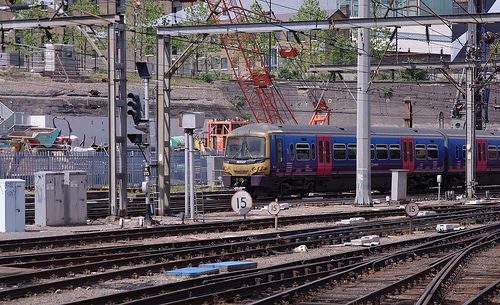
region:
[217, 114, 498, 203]
A red, yellow, blue and gray train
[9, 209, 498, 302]
A group of railroad tracks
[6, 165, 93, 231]
Three gray metal boxes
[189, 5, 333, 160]
A red construction vehicle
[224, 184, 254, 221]
Round sign with the number 15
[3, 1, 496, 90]
Trees and buildings behind a fence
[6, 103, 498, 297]
Train stopped at a railroad station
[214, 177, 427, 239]
Three circular signs with the number 15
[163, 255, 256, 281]
Two blue concrete squares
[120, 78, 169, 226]
Traffic light with no lights lit up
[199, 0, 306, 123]
red structure above train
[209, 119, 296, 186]
front of train is yellow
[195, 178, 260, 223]
the sign is white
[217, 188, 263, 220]
the sign is circular shaped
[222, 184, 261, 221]
black numbers on sign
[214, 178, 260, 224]
red circle around sign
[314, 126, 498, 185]
the train doors are red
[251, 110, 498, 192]
the train is blue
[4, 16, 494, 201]
structure is made of metal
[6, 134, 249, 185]
fence beside the train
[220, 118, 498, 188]
long blue,red, and yellow train on train tracks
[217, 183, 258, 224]
number 15 on round white sign on side of train tracks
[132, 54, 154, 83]
black hooded black box on side of train tracks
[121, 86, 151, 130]
three light black traffic signal on side of train tracks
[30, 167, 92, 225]
two metal boxes next to train tracks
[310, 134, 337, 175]
red doors on side of train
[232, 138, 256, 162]
windshield wipers on front windshield of train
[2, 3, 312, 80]
buildings above train tracks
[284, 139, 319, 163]
three windows on side of front of train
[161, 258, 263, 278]
blue panels on side of train tracks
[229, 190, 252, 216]
Large circle with number 15 in it.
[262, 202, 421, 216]
Small circles with number '15' in them.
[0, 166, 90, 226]
The grey boxes lined up together.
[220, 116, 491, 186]
Train riding down track.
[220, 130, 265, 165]
Front windshield of train.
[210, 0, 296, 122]
Large red crane up in air.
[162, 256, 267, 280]
Two blue squares in middle track.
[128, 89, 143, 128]
Black traffic signal on pole.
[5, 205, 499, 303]
Empty train tracks beside train.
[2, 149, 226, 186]
Blue picket fence beside train.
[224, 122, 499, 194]
a train going down the track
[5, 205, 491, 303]
the train tracks lying next to each other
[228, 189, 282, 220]
some signs standing next to the tracks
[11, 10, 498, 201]
some scaffolding above the tracks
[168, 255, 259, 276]
some blue covers next to the tracks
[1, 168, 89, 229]
some boxes filled with electrical wires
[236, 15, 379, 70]
some green leafy trees next to the buildings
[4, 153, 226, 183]
a fence next to the train tracks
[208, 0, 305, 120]
a red crane high in the air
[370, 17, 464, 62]
a blue and white wall